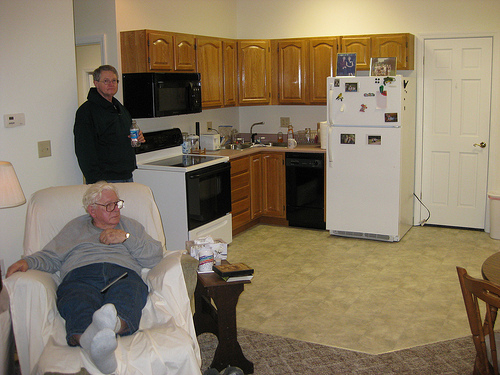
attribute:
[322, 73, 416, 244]
refrigerator — white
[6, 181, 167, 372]
man — old, sitting, standing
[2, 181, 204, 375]
recliner — white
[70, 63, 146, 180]
man — standing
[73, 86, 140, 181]
jacket — black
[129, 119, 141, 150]
beverage — clear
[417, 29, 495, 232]
door — white, closed, tall, wooden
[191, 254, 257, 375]
table — brown, small, wooden, dark, rectangular, wood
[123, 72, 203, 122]
microwave — black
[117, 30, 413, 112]
cupboards — brown, oak, wood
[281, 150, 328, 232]
dishwasher — black, small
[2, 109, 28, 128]
thermostat — white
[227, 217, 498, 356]
tile — cream colored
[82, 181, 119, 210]
hair — white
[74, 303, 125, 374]
socks — white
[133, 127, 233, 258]
range — white, black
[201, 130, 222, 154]
toaster — white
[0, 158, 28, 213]
lampshade — white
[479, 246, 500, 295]
table — wood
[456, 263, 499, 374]
chair — wood